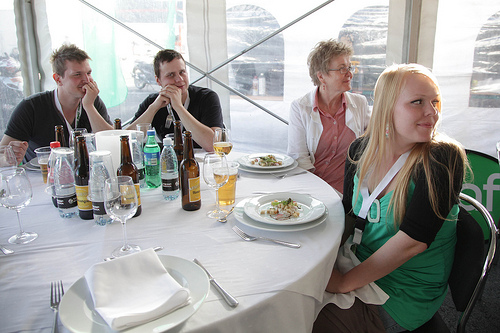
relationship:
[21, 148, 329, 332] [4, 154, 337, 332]
plates on table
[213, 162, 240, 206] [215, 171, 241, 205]
glass filled with drink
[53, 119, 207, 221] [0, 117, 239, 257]
bottles of drinks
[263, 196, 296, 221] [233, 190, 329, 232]
salad on plate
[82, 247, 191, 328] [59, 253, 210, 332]
napkin on top of plate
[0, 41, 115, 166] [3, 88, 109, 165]
men wearing shirts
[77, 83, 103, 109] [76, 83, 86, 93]
left hand covering mouth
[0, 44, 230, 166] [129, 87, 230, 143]
guys are wearing shirt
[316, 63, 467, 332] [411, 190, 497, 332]
woman sitting in chair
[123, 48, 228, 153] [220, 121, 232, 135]
guys sitting in chair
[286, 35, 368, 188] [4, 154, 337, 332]
woman sitting at table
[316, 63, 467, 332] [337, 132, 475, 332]
woman wearing shirt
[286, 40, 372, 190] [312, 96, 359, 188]
woman wearing shirt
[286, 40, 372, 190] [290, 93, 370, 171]
woman wearing sweater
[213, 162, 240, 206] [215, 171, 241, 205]
cup of beer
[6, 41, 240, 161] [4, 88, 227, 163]
men in shirts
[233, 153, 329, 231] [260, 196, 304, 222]
plates with salad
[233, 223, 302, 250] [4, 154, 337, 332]
fork on table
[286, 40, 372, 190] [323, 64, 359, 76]
woman wearing glasses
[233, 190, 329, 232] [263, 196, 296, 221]
plate has food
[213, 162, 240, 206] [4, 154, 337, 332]
glass on top of table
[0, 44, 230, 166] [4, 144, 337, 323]
men are having a meal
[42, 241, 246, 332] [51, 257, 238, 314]
setting with silverwear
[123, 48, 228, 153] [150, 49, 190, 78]
guys has hair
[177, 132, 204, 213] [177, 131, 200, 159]
bottle has a long neck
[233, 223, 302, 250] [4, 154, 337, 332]
fork on top of table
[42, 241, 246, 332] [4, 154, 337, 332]
setting on table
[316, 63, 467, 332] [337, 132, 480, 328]
woman wearing shirt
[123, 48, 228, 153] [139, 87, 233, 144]
guys wearing shirt